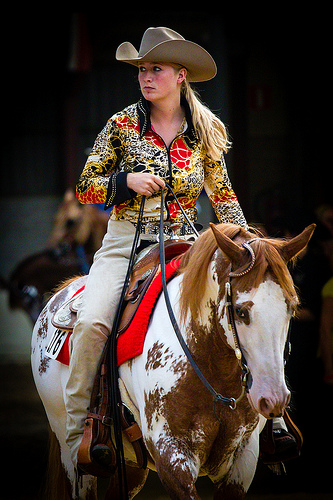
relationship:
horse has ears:
[30, 213, 318, 500] [208, 219, 313, 262]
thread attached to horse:
[108, 201, 191, 372] [30, 213, 329, 479]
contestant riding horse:
[65, 26, 248, 479] [32, 222, 316, 493]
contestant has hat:
[65, 26, 248, 479] [113, 12, 225, 82]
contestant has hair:
[65, 26, 248, 479] [170, 64, 232, 161]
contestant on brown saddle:
[65, 26, 248, 479] [119, 237, 198, 331]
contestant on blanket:
[65, 26, 248, 479] [53, 253, 186, 367]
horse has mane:
[30, 213, 329, 479] [173, 201, 298, 298]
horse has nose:
[30, 213, 318, 500] [249, 389, 297, 418]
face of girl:
[220, 268, 300, 412] [57, 27, 245, 466]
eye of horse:
[216, 284, 272, 343] [30, 213, 318, 500]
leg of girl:
[56, 267, 188, 473] [87, 11, 274, 312]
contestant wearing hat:
[65, 26, 248, 479] [115, 25, 217, 82]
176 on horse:
[46, 329, 65, 360] [32, 222, 316, 493]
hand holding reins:
[125, 168, 166, 199] [103, 174, 250, 416]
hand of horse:
[125, 168, 166, 199] [32, 222, 316, 493]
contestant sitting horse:
[65, 26, 248, 479] [30, 213, 329, 479]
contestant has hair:
[65, 26, 248, 479] [166, 72, 260, 150]